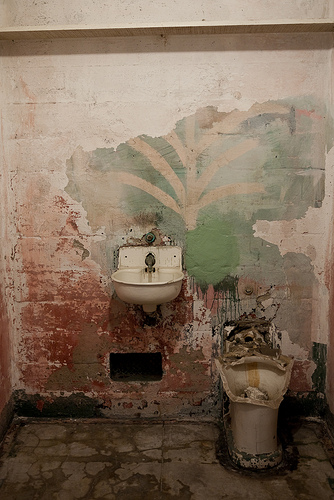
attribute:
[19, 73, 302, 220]
white bathroom — dirty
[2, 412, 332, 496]
floor — cracked, stained, concrete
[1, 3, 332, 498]
wall — white, red, green, brick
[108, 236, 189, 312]
sink — white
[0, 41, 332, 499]
bathroom — old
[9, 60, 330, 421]
wall — brick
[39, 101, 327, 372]
design — ruined, tree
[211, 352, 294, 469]
toilet bowl — missing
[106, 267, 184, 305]
bowl — missing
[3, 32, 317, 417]
wall/hole — red, white